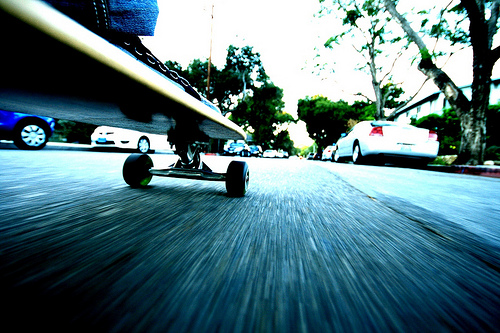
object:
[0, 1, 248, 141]
skateboard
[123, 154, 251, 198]
wheels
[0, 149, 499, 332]
street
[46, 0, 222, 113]
skater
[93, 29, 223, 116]
shoe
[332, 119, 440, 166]
sedan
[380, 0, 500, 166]
tree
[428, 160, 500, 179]
sidewalk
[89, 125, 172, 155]
sedan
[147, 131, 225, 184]
truck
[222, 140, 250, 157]
sedan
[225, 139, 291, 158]
cars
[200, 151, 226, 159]
sidewalk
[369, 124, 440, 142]
brakes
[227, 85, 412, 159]
trees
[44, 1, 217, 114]
person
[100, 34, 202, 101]
socks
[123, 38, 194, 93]
circles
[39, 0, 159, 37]
jeans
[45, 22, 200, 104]
foot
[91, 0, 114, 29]
seam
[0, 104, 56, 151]
vehicle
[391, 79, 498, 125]
house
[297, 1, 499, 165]
trees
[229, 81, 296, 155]
tree